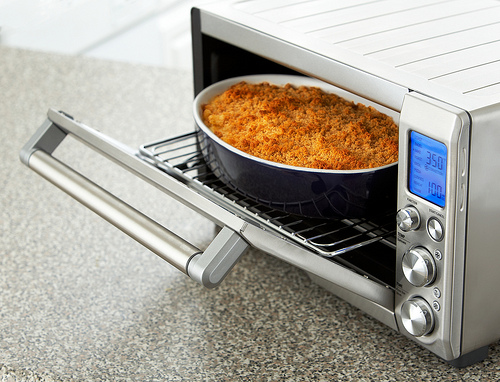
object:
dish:
[189, 75, 401, 217]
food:
[201, 83, 397, 167]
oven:
[20, 2, 500, 368]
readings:
[406, 130, 447, 206]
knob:
[401, 247, 437, 289]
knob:
[399, 298, 438, 338]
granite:
[0, 46, 498, 377]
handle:
[16, 115, 252, 287]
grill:
[139, 132, 399, 258]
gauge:
[401, 129, 449, 211]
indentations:
[360, 20, 497, 57]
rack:
[182, 160, 210, 174]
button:
[424, 217, 443, 242]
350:
[422, 152, 444, 169]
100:
[424, 180, 444, 197]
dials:
[393, 208, 422, 233]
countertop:
[0, 53, 499, 382]